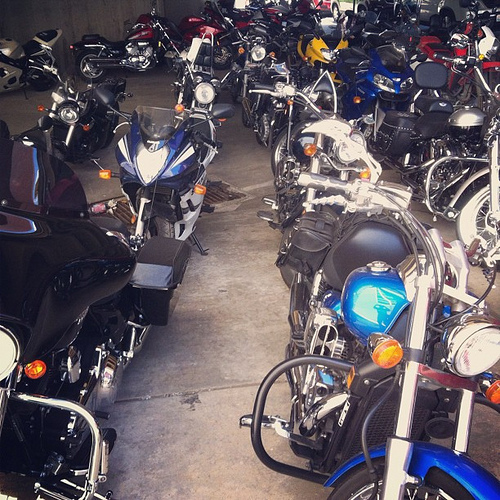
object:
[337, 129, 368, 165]
light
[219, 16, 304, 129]
motorcycle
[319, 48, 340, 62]
light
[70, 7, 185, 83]
motorcycle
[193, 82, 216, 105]
light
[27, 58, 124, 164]
motorcycle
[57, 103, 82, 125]
light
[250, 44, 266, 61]
light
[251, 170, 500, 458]
motorcycle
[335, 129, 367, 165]
headlight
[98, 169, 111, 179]
turn signal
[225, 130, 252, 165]
floor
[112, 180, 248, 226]
drain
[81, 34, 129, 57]
seat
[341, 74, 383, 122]
right side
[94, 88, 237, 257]
cycle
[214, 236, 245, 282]
dirt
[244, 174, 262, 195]
crack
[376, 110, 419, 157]
storage box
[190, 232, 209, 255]
kickstand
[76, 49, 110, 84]
rear tire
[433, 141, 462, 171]
side engine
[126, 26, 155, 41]
compartment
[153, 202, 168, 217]
gas tank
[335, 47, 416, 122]
stripes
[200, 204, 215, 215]
grate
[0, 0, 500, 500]
photo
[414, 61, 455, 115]
saddlebags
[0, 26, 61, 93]
bike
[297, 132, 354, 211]
sissy bar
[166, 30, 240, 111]
motorcycles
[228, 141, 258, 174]
street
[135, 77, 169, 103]
ground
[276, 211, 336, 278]
box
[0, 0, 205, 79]
wall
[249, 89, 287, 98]
handle